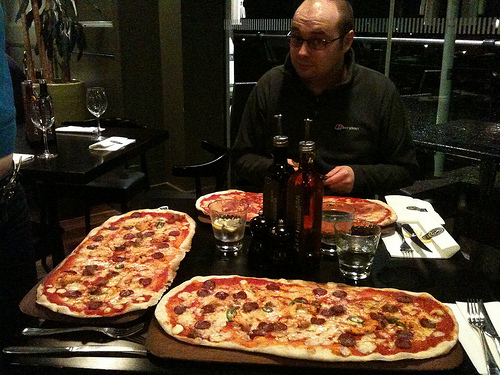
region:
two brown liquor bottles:
[255, 102, 326, 262]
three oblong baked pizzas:
[56, 160, 461, 355]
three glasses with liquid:
[200, 180, 390, 265]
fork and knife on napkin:
[445, 281, 495, 361]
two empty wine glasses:
[25, 85, 125, 145]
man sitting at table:
[215, 0, 420, 270]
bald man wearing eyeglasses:
[261, 0, 366, 95]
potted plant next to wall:
[10, 6, 101, 126]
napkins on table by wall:
[10, 77, 136, 177]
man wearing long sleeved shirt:
[230, 55, 425, 210]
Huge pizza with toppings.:
[162, 274, 450, 365]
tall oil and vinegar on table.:
[260, 96, 340, 258]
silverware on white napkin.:
[460, 298, 499, 373]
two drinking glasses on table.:
[322, 203, 394, 277]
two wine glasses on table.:
[25, 81, 109, 161]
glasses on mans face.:
[287, 24, 352, 52]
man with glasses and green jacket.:
[0, 8, 496, 148]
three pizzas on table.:
[40, 180, 476, 360]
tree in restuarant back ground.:
[27, 3, 102, 120]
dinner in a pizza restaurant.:
[18, 1, 498, 358]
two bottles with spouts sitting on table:
[245, 110, 345, 274]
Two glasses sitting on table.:
[314, 194, 386, 284]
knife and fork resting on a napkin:
[450, 294, 498, 373]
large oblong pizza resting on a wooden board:
[141, 257, 468, 369]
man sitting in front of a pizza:
[211, 0, 421, 231]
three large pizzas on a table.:
[7, 184, 498, 371]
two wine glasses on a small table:
[16, 75, 126, 172]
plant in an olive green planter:
[0, 3, 120, 138]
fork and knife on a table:
[0, 312, 169, 364]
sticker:
[417, 226, 455, 245]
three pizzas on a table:
[42, 185, 458, 361]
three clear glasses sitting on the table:
[206, 197, 383, 275]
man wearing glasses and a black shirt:
[261, 1, 416, 186]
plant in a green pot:
[18, 2, 95, 123]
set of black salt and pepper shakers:
[246, 209, 293, 269]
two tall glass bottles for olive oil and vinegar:
[267, 112, 323, 264]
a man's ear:
[343, 27, 354, 52]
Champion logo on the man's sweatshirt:
[333, 121, 362, 134]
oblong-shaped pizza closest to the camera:
[156, 271, 463, 363]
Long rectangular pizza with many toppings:
[172, 274, 457, 363]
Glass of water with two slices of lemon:
[201, 196, 256, 255]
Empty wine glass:
[79, 79, 114, 144]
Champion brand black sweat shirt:
[237, 60, 422, 195]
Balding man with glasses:
[257, 0, 374, 87]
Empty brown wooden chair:
[135, 130, 237, 205]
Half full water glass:
[330, 214, 385, 289]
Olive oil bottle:
[283, 110, 333, 268]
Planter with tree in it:
[10, 4, 92, 127]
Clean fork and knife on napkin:
[452, 294, 499, 369]